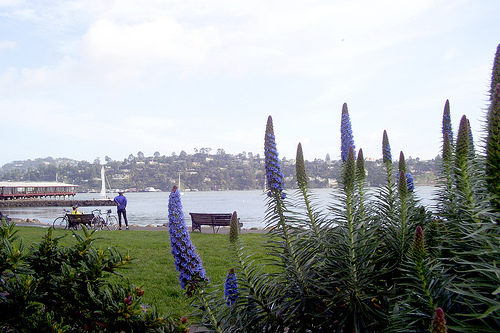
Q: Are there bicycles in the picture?
A: Yes, there is a bicycle.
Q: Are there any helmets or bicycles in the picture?
A: Yes, there is a bicycle.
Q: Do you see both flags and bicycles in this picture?
A: No, there is a bicycle but no flags.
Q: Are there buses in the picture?
A: No, there are no buses.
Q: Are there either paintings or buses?
A: No, there are no buses or paintings.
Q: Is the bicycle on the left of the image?
A: Yes, the bicycle is on the left of the image.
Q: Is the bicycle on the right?
A: No, the bicycle is on the left of the image.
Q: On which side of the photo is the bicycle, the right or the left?
A: The bicycle is on the left of the image.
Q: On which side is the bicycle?
A: The bicycle is on the left of the image.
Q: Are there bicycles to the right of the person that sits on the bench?
A: Yes, there is a bicycle to the right of the person.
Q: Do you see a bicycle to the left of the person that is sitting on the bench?
A: No, the bicycle is to the right of the person.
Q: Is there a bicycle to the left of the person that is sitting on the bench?
A: No, the bicycle is to the right of the person.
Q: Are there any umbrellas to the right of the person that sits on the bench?
A: No, there is a bicycle to the right of the person.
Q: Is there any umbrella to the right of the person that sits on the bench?
A: No, there is a bicycle to the right of the person.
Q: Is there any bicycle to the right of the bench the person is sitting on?
A: Yes, there is a bicycle to the right of the bench.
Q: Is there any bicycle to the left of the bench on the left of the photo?
A: No, the bicycle is to the right of the bench.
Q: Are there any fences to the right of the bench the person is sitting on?
A: No, there is a bicycle to the right of the bench.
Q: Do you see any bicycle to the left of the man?
A: Yes, there is a bicycle to the left of the man.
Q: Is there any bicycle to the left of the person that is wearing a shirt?
A: Yes, there is a bicycle to the left of the man.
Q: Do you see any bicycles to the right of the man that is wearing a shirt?
A: No, the bicycle is to the left of the man.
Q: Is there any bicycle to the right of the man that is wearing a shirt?
A: No, the bicycle is to the left of the man.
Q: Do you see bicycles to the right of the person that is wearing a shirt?
A: No, the bicycle is to the left of the man.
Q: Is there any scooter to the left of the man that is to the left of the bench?
A: No, there is a bicycle to the left of the man.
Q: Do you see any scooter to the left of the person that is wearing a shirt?
A: No, there is a bicycle to the left of the man.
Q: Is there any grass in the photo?
A: Yes, there is grass.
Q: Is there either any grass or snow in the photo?
A: Yes, there is grass.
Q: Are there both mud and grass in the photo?
A: No, there is grass but no mud.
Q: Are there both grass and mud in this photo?
A: No, there is grass but no mud.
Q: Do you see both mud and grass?
A: No, there is grass but no mud.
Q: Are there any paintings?
A: No, there are no paintings.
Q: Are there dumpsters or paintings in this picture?
A: No, there are no paintings or dumpsters.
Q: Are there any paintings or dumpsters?
A: No, there are no paintings or dumpsters.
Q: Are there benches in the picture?
A: Yes, there is a bench.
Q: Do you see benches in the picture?
A: Yes, there is a bench.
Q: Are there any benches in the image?
A: Yes, there is a bench.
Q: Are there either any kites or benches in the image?
A: Yes, there is a bench.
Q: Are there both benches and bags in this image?
A: No, there is a bench but no bags.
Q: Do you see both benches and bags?
A: No, there is a bench but no bags.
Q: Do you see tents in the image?
A: No, there are no tents.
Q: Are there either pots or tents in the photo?
A: No, there are no tents or pots.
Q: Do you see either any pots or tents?
A: No, there are no tents or pots.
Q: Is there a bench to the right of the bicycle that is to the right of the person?
A: Yes, there is a bench to the right of the bicycle.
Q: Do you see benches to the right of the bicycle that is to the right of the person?
A: Yes, there is a bench to the right of the bicycle.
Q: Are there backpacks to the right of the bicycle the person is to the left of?
A: No, there is a bench to the right of the bicycle.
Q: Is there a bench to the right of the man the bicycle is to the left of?
A: Yes, there is a bench to the right of the man.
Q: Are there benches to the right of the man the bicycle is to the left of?
A: Yes, there is a bench to the right of the man.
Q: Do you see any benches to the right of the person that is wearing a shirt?
A: Yes, there is a bench to the right of the man.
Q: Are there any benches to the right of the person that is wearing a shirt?
A: Yes, there is a bench to the right of the man.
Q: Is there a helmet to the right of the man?
A: No, there is a bench to the right of the man.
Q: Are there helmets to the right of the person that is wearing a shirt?
A: No, there is a bench to the right of the man.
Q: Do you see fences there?
A: No, there are no fences.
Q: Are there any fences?
A: No, there are no fences.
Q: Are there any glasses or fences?
A: No, there are no fences or glasses.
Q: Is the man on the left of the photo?
A: Yes, the man is on the left of the image.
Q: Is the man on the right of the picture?
A: No, the man is on the left of the image.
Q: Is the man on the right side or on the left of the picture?
A: The man is on the left of the image.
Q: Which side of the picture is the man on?
A: The man is on the left of the image.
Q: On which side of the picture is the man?
A: The man is on the left of the image.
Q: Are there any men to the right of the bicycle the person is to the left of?
A: Yes, there is a man to the right of the bicycle.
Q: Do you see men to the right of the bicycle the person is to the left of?
A: Yes, there is a man to the right of the bicycle.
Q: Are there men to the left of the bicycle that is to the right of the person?
A: No, the man is to the right of the bicycle.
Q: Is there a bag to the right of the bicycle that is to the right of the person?
A: No, there is a man to the right of the bicycle.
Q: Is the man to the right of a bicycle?
A: Yes, the man is to the right of a bicycle.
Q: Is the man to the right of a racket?
A: No, the man is to the right of a bicycle.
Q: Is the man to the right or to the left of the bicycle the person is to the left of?
A: The man is to the right of the bicycle.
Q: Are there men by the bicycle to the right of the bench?
A: Yes, there is a man by the bicycle.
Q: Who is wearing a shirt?
A: The man is wearing a shirt.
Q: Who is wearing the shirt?
A: The man is wearing a shirt.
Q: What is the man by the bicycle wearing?
A: The man is wearing a shirt.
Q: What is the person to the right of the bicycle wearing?
A: The man is wearing a shirt.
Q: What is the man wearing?
A: The man is wearing a shirt.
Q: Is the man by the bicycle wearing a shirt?
A: Yes, the man is wearing a shirt.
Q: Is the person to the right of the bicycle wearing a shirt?
A: Yes, the man is wearing a shirt.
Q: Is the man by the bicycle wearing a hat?
A: No, the man is wearing a shirt.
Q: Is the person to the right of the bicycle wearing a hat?
A: No, the man is wearing a shirt.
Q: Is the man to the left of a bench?
A: Yes, the man is to the left of a bench.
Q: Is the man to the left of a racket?
A: No, the man is to the left of a bench.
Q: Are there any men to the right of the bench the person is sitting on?
A: Yes, there is a man to the right of the bench.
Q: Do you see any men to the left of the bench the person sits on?
A: No, the man is to the right of the bench.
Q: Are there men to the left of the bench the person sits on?
A: No, the man is to the right of the bench.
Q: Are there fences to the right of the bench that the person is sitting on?
A: No, there is a man to the right of the bench.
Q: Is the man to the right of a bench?
A: Yes, the man is to the right of a bench.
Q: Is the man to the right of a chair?
A: No, the man is to the right of a bench.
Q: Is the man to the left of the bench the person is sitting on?
A: No, the man is to the right of the bench.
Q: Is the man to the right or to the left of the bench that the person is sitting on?
A: The man is to the right of the bench.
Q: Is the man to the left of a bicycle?
A: No, the man is to the right of a bicycle.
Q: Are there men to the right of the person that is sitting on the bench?
A: Yes, there is a man to the right of the person.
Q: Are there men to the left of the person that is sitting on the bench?
A: No, the man is to the right of the person.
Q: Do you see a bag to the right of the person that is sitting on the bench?
A: No, there is a man to the right of the person.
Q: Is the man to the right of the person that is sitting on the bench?
A: Yes, the man is to the right of the person.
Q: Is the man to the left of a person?
A: No, the man is to the right of a person.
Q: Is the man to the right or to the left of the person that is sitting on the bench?
A: The man is to the right of the person.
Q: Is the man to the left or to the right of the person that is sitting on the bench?
A: The man is to the right of the person.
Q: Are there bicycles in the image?
A: Yes, there is a bicycle.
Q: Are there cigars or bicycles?
A: Yes, there is a bicycle.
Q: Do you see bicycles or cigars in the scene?
A: Yes, there is a bicycle.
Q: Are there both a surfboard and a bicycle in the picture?
A: No, there is a bicycle but no surfboards.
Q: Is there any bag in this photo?
A: No, there are no bags.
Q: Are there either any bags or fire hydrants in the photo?
A: No, there are no bags or fire hydrants.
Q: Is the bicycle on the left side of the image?
A: Yes, the bicycle is on the left of the image.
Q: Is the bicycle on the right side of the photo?
A: No, the bicycle is on the left of the image.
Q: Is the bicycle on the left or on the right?
A: The bicycle is on the left of the image.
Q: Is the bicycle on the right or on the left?
A: The bicycle is on the left of the image.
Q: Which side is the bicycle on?
A: The bicycle is on the left of the image.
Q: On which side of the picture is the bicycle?
A: The bicycle is on the left of the image.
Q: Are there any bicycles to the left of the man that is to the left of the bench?
A: Yes, there is a bicycle to the left of the man.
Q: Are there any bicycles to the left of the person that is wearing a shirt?
A: Yes, there is a bicycle to the left of the man.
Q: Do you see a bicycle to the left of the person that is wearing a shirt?
A: Yes, there is a bicycle to the left of the man.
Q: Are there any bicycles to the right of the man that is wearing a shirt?
A: No, the bicycle is to the left of the man.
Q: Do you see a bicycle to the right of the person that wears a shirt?
A: No, the bicycle is to the left of the man.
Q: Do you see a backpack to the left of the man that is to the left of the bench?
A: No, there is a bicycle to the left of the man.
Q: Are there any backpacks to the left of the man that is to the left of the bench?
A: No, there is a bicycle to the left of the man.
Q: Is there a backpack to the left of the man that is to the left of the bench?
A: No, there is a bicycle to the left of the man.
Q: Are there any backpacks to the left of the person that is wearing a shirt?
A: No, there is a bicycle to the left of the man.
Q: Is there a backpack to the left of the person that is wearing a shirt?
A: No, there is a bicycle to the left of the man.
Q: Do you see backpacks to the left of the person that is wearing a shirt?
A: No, there is a bicycle to the left of the man.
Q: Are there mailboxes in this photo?
A: No, there are no mailboxes.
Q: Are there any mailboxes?
A: No, there are no mailboxes.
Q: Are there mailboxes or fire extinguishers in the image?
A: No, there are no mailboxes or fire extinguishers.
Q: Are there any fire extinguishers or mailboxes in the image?
A: No, there are no mailboxes or fire extinguishers.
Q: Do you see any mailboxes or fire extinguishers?
A: No, there are no mailboxes or fire extinguishers.